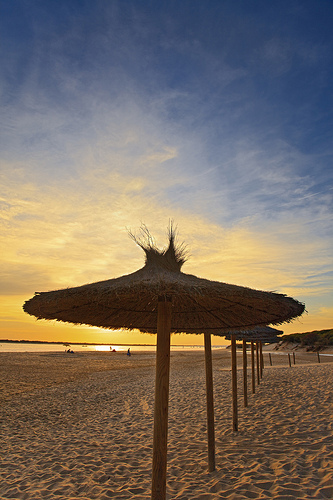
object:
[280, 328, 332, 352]
grass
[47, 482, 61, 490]
footprint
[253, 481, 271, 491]
footprint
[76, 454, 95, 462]
footprint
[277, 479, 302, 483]
footprint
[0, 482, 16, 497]
footprint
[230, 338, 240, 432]
pole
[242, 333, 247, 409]
pole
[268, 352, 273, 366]
pole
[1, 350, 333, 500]
sand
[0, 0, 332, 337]
sky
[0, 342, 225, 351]
water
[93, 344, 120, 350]
reflection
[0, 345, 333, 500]
shore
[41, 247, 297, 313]
roof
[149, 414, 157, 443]
edge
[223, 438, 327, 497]
foot prints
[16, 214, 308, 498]
umbrella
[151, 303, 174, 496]
poles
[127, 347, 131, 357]
people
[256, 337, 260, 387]
wood pole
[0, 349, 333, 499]
beach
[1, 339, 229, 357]
ocean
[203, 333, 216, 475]
pole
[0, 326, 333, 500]
sandy beach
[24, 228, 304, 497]
huts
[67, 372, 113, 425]
part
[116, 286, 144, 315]
part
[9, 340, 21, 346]
part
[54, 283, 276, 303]
edge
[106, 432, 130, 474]
part